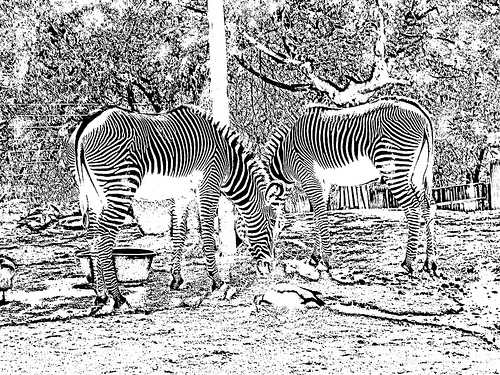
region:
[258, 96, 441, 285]
zebra to the right of zebra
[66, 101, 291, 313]
zebra to the left of zebra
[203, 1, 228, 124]
tall pole behind zebra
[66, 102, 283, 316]
zebra in front of pole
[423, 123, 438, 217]
long zebra tail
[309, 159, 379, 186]
underside of zebra is white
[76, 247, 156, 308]
bucket behind zebra leg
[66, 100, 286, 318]
zebra is eating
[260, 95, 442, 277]
zebra standing on the ground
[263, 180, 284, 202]
zebra ear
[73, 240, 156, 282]
A large metal pan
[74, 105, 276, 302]
A zebra grazing on grass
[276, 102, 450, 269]
A zebra standing by a pole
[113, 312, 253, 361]
Dirt beneath the zebra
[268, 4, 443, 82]
Trees behind the pole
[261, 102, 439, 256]
The zebra is black and white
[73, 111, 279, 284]
The zebra has stripes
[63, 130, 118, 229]
A drooping zebra tail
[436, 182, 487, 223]
A wooden fence in the distance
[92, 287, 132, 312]
Black zebra hooves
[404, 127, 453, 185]
tail of a zebra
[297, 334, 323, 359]
part of a ground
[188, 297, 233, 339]
part of a ground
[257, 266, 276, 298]
part of a mouth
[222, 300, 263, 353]
part of a ground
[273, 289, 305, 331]
part of a stone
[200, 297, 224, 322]
part of a groun d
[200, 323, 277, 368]
this is the ground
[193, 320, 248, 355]
the ground is clean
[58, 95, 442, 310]
these are two zebras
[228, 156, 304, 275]
the zebras are feeding on grass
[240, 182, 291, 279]
this is the zebra's head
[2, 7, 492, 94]
these are several trees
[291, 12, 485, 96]
the trees are tall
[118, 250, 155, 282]
this is a basin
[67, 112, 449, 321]
the zebras are standing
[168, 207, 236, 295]
the feet are apart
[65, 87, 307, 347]
a zebra bent down eating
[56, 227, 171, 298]
a bowl next to the zebra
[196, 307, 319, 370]
grass on the ground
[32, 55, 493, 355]
two zebras eating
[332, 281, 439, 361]
crack in the ground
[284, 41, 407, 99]
tree branches in the air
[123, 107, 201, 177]
black and white striped fur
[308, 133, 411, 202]
zebra underbelly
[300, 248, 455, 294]
zebra hooves on the ground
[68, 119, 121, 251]
zebra tail